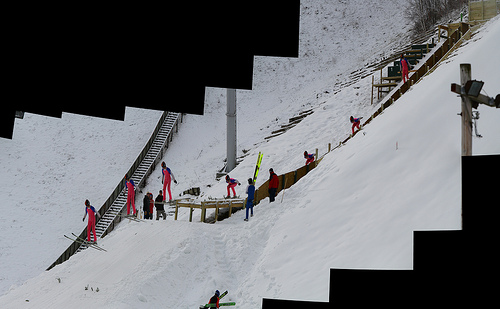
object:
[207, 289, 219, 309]
skier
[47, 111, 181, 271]
tracks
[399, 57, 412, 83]
ski outfit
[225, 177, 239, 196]
ski suite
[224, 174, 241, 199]
person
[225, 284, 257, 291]
ski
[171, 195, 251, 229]
lift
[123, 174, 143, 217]
person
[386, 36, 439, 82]
outfi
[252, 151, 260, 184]
pole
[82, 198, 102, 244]
person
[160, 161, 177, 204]
person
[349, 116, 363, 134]
skier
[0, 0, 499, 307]
hill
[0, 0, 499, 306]
snow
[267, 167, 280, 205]
person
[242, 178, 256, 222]
person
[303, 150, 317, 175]
person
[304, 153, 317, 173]
ski suit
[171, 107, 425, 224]
platform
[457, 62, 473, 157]
pole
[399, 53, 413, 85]
person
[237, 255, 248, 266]
skis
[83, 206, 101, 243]
ski suit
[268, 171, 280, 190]
ski suit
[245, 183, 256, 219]
ski suit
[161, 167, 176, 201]
ski suit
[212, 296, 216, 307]
arm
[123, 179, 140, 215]
suit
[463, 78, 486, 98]
object